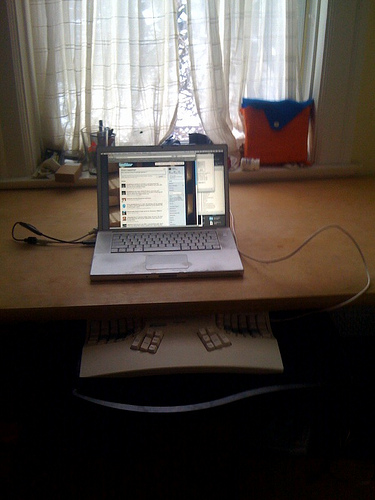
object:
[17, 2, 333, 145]
window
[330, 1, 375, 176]
wall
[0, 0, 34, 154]
wall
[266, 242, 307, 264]
white cord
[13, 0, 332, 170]
background window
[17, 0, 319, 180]
curtain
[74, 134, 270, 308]
laptop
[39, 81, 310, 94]
stripes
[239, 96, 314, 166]
bag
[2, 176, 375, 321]
computer desk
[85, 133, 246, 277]
computer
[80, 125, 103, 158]
glass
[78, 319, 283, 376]
keyboard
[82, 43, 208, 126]
sunlight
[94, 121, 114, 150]
pens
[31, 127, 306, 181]
sill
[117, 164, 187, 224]
twitter